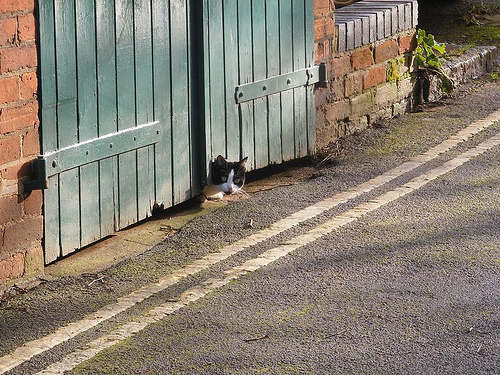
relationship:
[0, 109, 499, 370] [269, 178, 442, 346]
line on ground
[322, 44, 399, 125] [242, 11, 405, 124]
bricks on a building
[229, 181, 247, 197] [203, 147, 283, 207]
whiskers on cat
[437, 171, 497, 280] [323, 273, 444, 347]
shadows on ground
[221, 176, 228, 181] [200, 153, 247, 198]
eye on a cat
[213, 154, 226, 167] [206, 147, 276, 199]
ear connected to cat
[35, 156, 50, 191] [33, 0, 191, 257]
hinge connected to door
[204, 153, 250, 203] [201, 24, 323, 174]
cat underneath door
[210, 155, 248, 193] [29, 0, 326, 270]
cat's head underneath door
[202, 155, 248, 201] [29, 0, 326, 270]
cat underneath door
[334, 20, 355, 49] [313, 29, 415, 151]
bricks on top of wall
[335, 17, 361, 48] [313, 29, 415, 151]
bricks on top of wall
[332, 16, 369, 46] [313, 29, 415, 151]
bricks on top of wall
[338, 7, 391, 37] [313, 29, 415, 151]
bricks on top of wall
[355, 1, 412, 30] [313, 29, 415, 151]
bricks on top of wall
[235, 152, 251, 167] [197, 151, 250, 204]
ear connected to cat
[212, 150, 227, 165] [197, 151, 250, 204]
ear connected to cat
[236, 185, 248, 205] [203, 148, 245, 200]
whiskers connected to cat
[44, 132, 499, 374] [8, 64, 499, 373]
line painted on ground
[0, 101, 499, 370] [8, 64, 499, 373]
line painted on ground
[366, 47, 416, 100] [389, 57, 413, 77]
moss growing from brick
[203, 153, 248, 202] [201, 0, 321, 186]
cat's head stuck under door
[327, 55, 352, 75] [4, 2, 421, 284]
brick connected to building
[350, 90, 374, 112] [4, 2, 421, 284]
brick connected to building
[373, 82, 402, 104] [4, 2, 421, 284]
brick connected to building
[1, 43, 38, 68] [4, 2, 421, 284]
brick connected to building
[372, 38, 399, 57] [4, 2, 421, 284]
brick connected to building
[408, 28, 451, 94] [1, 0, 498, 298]
plant growing next to building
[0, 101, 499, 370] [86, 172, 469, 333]
line on ground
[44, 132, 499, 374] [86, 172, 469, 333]
line on ground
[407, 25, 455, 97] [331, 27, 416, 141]
plant near bricks